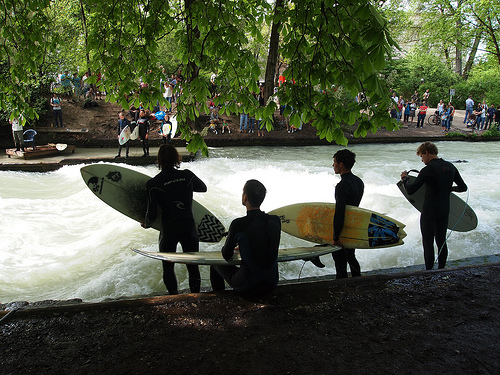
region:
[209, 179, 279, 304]
Man sitting under tree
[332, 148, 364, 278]
Man holding surfboard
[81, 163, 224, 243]
White surfboard with black designs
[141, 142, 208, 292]
Man standing in water holding surfboard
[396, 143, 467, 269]
Man fixin strap on surfboard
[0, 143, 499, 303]
River of water in between surfers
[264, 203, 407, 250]
Yellow surboard with bluee flower on tail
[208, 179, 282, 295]
Man sitting behind another in the water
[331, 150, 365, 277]
Man standing wearing black wetsuit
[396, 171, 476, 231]
White surfboard held by man wearing black wetsuit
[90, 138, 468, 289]
The all have surfboards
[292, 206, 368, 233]
The surfboard is yellow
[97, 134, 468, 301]
They all have wetsuits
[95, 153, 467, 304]
They are waiting to surf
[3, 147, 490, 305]
The waves are on a river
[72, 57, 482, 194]
There are many people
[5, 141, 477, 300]
The river has waves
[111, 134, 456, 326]
Their wetsuits are black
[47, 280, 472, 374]
The ground is full of dirt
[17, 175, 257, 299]
the waves produce white foam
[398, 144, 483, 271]
Man holding a surfboard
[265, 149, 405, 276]
Man holding a surfboard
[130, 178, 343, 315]
Man sitting with surfboard on lap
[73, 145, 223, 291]
Man holding a surfboard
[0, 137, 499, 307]
Rushing white water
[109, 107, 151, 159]
Two men holding surfboards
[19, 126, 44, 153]
Blue lawn chair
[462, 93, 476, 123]
Man with back turned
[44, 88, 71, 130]
Man standing on other side of water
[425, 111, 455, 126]
Bicycle blocked by people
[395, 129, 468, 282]
PErson wearing a black wet suite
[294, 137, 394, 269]
PErson wearing a black wet suite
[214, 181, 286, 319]
PErson wearing a black wet suite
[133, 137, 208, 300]
PErson wearing a black wet suite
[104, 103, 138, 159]
PErson wearing a black wet suite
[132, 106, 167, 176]
PErson wearing a black wet suite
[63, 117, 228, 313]
PErson holding a surfboard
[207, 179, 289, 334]
PErson holding a surfboard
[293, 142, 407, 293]
PErson holding a surfboard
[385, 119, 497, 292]
PErson holding a surfboard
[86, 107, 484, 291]
four men holding surf boards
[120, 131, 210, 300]
a man holding a surf board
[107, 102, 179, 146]
two men holding surf boards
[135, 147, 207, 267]
a man wearing a wetsuit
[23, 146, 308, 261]
fast running water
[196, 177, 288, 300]
a man sitting by water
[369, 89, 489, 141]
several people standing together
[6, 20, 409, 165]
tree limbs hanging over the water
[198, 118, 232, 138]
two children sitting on the ground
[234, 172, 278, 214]
a man with short hair